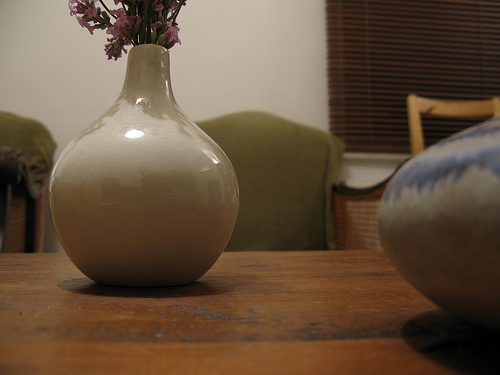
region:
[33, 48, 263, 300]
white vase on table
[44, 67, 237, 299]
round bottom to vase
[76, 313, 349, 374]
brown and black wooden table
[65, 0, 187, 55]
green and pink flowers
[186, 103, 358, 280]
green backing to chair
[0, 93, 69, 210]
back of chair brown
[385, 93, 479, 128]
brown back piece of chair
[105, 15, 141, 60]
light pink flowers from vase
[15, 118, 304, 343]
vase on top of table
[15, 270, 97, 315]
black shadow from vase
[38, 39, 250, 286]
the vase is shiney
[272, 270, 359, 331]
the table is brown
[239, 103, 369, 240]
the chair is green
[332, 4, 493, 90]
the blinds are brown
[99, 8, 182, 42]
the flowers are purple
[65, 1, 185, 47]
the flowers are in a vase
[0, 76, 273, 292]
the vase is tan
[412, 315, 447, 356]
the shadow is on the table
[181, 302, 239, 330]
the table has black grooves in it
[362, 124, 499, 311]
the vase is rounded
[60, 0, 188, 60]
purple flowers in vase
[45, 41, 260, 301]
white flower vase sitting on table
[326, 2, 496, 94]
brown window blinds hanging on window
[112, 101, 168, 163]
reflection of light on white vase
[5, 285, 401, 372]
brown wooden table top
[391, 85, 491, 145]
back of brown wooden chair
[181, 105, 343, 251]
back of green chair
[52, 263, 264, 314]
shadow of vase on table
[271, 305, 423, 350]
black stain on brown table top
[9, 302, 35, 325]
small black speck on brown table top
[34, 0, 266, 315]
a vase on the table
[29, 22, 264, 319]
the vase is white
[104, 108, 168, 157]
the light is reflected in the vase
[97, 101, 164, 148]
the light is on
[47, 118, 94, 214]
a bookshelf reflected in the vase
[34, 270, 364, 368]
the table is brown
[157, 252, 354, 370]
the table is made of wood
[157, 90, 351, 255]
the chair is empty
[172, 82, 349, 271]
the chair is green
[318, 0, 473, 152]
the blinds are down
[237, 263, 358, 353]
dark wood stained table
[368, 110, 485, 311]
rounded vase with black stains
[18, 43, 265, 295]
rounded beige flower vase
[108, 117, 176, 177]
light shinning on vase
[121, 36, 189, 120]
narrow opening on vase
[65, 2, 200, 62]
violet colored small flowers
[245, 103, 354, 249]
dark green seat cover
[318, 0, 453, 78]
dark wood colored shutters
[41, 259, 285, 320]
shadow of a vase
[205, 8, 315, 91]
white plain smooth wall